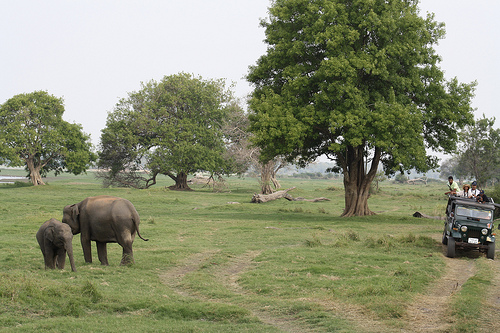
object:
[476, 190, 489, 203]
people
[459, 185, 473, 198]
people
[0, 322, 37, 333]
grass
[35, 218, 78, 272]
elephant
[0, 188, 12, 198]
grass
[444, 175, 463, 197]
men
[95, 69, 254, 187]
tree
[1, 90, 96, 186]
tree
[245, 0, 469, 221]
trees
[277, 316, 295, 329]
dirt path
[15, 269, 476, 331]
ground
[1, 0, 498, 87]
sky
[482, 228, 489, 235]
headlight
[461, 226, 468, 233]
headlight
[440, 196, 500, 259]
jeep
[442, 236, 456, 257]
wheels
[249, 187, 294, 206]
tree trunk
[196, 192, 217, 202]
grass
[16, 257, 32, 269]
grass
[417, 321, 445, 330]
rut marks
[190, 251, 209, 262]
rut marks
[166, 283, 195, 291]
rut marks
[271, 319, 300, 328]
rut marks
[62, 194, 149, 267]
elephant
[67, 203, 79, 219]
ear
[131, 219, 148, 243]
tail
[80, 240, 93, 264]
legs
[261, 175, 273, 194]
trunk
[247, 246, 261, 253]
marks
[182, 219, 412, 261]
field